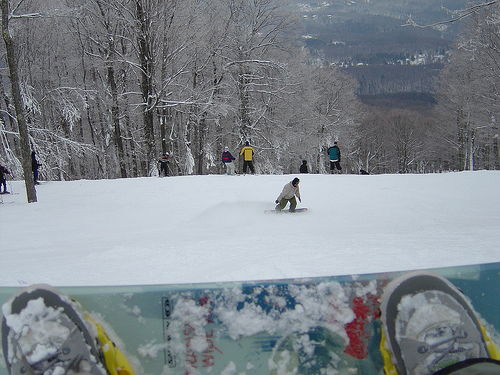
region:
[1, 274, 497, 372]
a pair of snow covered sneakers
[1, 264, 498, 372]
the top of a snow board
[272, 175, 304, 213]
a snow boarder wearing all gray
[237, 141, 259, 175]
a snow boarder in a yellow coat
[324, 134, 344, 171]
a snow boarder in a blue coat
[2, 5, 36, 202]
a gray tree trunk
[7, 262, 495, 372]
snow board of person taking the photo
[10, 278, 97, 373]
snowboarders left foot in boot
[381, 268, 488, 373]
snowboarders right foot in boot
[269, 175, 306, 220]
snowboarder in motion on slope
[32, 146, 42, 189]
person resting in the trees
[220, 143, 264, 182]
two snowboarders standing near tree at edge of slope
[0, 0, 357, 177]
leaf bare trees lines with frost and snow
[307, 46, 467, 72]
buildings in the far distance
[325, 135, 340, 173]
man in green coat looking at slope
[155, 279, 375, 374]
graphics partly hidden by snow and ice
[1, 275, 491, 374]
A snowboarder's feet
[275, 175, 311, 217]
A peron riding a snow board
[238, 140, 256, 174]
A person wear a yellow coat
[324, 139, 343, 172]
A person wearing a blue coat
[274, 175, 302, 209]
A person wearing a gray coat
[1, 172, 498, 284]
Snow covering the ground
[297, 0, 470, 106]
An opening in the trees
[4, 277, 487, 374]
Two gray shoes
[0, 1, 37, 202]
A tree by itself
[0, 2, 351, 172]
A group of trees in background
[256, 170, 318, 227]
a person snowboarding downhill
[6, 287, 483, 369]
the edge of a snowboard in the foreground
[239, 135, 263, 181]
a person wearing yellow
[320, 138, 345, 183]
a person wearing green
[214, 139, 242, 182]
a person wearing blue and red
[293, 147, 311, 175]
a person wearing black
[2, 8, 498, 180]
a row of trees running downhill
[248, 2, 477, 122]
a mountainside across a valley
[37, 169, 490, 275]
a snowcovered hillside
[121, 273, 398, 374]
snow caked on the edge of a snowboard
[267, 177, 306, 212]
person on a snowboard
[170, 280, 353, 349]
snow on the board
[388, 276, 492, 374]
the shoe of someone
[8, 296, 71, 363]
snow on the shoe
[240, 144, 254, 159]
the jacket is yellow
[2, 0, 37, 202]
trunk of a tree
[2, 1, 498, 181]
trees covered with snow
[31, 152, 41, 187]
someone is standing around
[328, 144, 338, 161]
the jacket is green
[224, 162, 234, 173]
the pants are white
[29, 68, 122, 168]
branches covered with snow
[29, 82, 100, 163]
branches covered with snow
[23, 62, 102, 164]
branches covered with snow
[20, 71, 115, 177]
branches covered with snow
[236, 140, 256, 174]
person in a yellow jacket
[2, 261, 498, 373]
sneakers on a snowboard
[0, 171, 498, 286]
snow on the ground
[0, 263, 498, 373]
snow on the snowboard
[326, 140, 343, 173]
person wearing green jacket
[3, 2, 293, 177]
snow on tree branches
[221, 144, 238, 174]
person wearing red and blue jacket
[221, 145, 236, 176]
person wearing white pants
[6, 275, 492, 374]
snow on the sneakers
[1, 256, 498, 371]
snow board with tops of two shoes on it